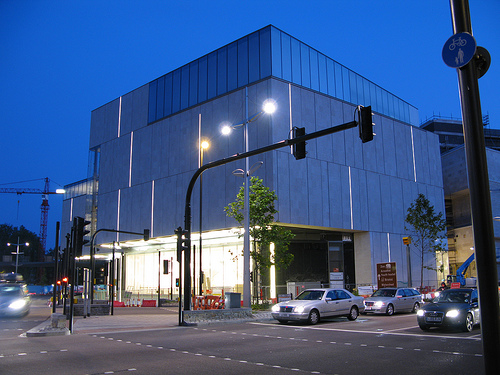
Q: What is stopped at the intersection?
A: Vehicles.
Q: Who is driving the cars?
A: Adults.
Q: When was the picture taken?
A: Night.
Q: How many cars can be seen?
A: Four.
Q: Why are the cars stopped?
A: Red light.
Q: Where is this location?
A: Intersection.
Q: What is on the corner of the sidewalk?
A: Building.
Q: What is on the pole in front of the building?
A: Lights.